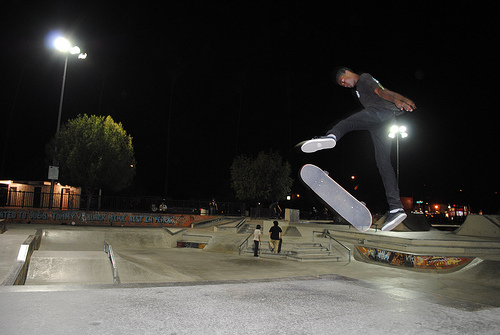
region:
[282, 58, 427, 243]
skateboarder in the air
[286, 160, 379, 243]
skateboard in the air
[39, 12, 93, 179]
street light shining over the park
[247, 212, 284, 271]
people with skateboards at the park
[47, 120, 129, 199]
tree by the skate park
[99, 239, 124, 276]
railing at the skate park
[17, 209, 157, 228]
graffiti on the wall at the skate park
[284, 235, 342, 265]
steps in the skate park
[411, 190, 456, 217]
buildings in the distance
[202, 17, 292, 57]
pitch black night sky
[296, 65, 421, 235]
skateboarder doing a trick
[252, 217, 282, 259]
people walking up the stairs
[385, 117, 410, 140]
street light behind the skater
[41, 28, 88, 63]
street light to the left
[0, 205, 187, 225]
graffiti on the wall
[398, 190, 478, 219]
traffic signals in the background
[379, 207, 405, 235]
black skate shoe with a white sole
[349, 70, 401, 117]
a black tshirt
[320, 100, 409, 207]
a black pair of pants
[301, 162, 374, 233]
white skateboard in mid air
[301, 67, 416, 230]
man with skateboard in mid air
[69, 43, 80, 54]
light on post is on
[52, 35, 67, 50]
light on post is on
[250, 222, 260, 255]
Person wearing white shirt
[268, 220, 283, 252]
person holding skateboard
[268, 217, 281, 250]
person wearing black shirt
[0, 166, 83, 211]
dimly lit building under light post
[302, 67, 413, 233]
Man wearing black pants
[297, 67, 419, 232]
The man is skateboarding.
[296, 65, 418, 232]
The skateboarder is airborne.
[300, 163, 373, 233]
The skateboard is white.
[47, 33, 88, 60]
The light is illuminated.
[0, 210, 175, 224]
Graffiti is on the wall.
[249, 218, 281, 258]
Two people walk up the steps.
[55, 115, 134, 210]
A tree is next to the skateboard park.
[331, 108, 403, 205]
The skateboarder's pants are black.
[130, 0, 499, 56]
The sky is dark.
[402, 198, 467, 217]
City lights are in the background.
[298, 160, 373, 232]
White skateboard for athlete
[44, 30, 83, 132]
Night light on pole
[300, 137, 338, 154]
Bottom of athlete's shoe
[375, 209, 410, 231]
Side of athlere's shoe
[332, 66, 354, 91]
Head of talented athletre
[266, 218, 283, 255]
Standing person with skateboard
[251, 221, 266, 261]
Individual talking to skateboard person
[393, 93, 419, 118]
Hand of athletic skateboard person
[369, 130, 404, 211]
Leg of athletic person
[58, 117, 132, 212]
Summer leafed out tree